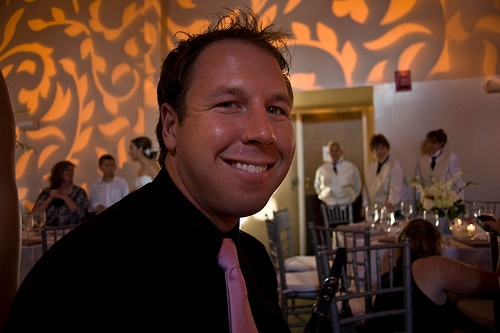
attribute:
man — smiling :
[0, 6, 296, 331]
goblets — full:
[364, 199, 442, 229]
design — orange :
[13, 41, 59, 114]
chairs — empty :
[265, 211, 327, 295]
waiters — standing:
[309, 121, 469, 221]